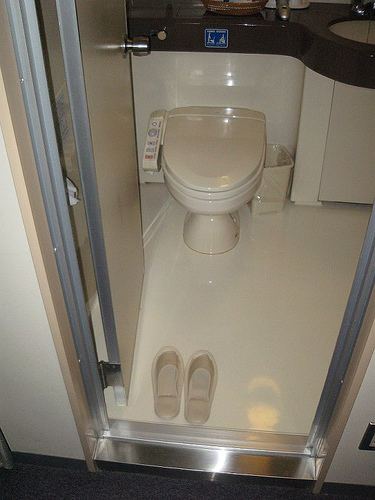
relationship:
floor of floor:
[91, 199, 372, 434] [91, 199, 372, 434]